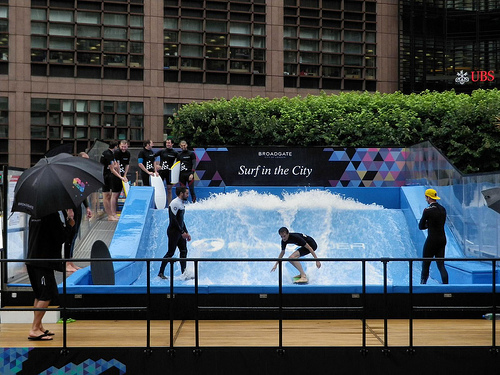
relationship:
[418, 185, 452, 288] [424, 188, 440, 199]
man has cap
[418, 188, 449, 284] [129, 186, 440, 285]
man surfing on water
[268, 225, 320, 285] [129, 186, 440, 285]
man surfing on water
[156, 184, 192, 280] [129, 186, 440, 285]
man surfing on water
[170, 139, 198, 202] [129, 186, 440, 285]
man surfing on water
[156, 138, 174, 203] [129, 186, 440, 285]
man surfing on water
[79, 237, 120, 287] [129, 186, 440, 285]
board in water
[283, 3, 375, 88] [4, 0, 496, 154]
windows on building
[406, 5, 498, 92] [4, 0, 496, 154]
windows on building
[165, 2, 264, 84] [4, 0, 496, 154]
windows on building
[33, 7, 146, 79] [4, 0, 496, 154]
windows on building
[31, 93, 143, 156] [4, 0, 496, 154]
windows on building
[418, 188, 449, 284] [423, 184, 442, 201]
man wearing cap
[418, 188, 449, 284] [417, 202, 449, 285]
man wearing wetsuit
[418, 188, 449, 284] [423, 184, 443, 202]
man wearing hat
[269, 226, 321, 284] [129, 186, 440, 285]
man in water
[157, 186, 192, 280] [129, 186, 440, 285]
man in water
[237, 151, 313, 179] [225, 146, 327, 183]
lettering on sign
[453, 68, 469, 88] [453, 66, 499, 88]
logo on sign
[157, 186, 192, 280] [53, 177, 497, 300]
man in pool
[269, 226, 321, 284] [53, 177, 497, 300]
man in pool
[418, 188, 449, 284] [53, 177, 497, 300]
man in pool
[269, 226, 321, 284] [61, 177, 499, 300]
man in pool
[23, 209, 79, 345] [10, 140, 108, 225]
person holding umbrella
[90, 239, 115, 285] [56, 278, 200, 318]
board on pool edge